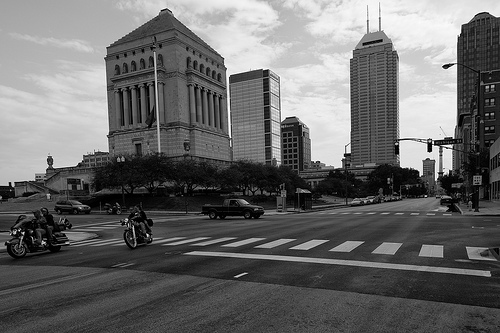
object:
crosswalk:
[70, 236, 500, 261]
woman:
[40, 207, 56, 242]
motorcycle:
[6, 227, 71, 258]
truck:
[201, 197, 265, 219]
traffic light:
[394, 141, 401, 155]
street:
[0, 195, 500, 332]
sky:
[1, 0, 499, 186]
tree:
[90, 154, 156, 194]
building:
[107, 7, 233, 170]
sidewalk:
[454, 194, 499, 216]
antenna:
[366, 4, 370, 34]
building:
[350, 32, 399, 175]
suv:
[54, 199, 92, 215]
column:
[189, 84, 197, 123]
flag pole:
[152, 44, 162, 158]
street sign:
[434, 139, 463, 146]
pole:
[396, 137, 481, 212]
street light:
[440, 62, 480, 213]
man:
[26, 209, 47, 245]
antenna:
[378, 2, 382, 32]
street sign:
[473, 175, 482, 186]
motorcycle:
[119, 218, 152, 249]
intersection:
[106, 212, 485, 251]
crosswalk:
[284, 210, 462, 216]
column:
[121, 87, 132, 127]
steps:
[13, 167, 61, 195]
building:
[228, 69, 282, 167]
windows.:
[242, 82, 248, 85]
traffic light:
[427, 138, 433, 153]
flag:
[144, 105, 157, 128]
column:
[114, 88, 122, 128]